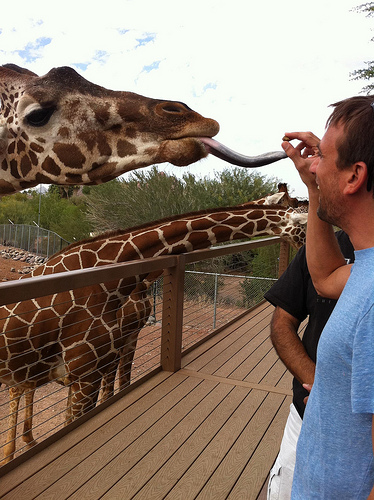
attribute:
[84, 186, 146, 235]
tree — Green, tall, leafy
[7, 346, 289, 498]
deck — brown, wooden 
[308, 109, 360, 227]
face — man's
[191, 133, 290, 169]
tongue — black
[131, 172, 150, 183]
leaves — Green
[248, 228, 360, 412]
shirt — black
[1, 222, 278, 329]
fence — Gray, chain link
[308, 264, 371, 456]
t-shirt — blue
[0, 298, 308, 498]
wooden deck — Brown 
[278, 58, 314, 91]
white cloud — White 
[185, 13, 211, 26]
white cloud — White 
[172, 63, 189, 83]
white cloud — White 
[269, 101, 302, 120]
white cloud — White 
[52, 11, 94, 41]
white cloud — White 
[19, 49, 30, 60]
blue sky — Blue 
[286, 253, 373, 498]
shirt — blue 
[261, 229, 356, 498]
guy — white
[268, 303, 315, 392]
arm — hairy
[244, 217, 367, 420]
shirt — black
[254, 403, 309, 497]
pants — khaki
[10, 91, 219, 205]
giraffe — brown, tan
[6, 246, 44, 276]
rocks — Large, gray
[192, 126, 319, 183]
tongue — long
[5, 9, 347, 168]
clouds — White 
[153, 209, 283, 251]
spots — Brown , white 